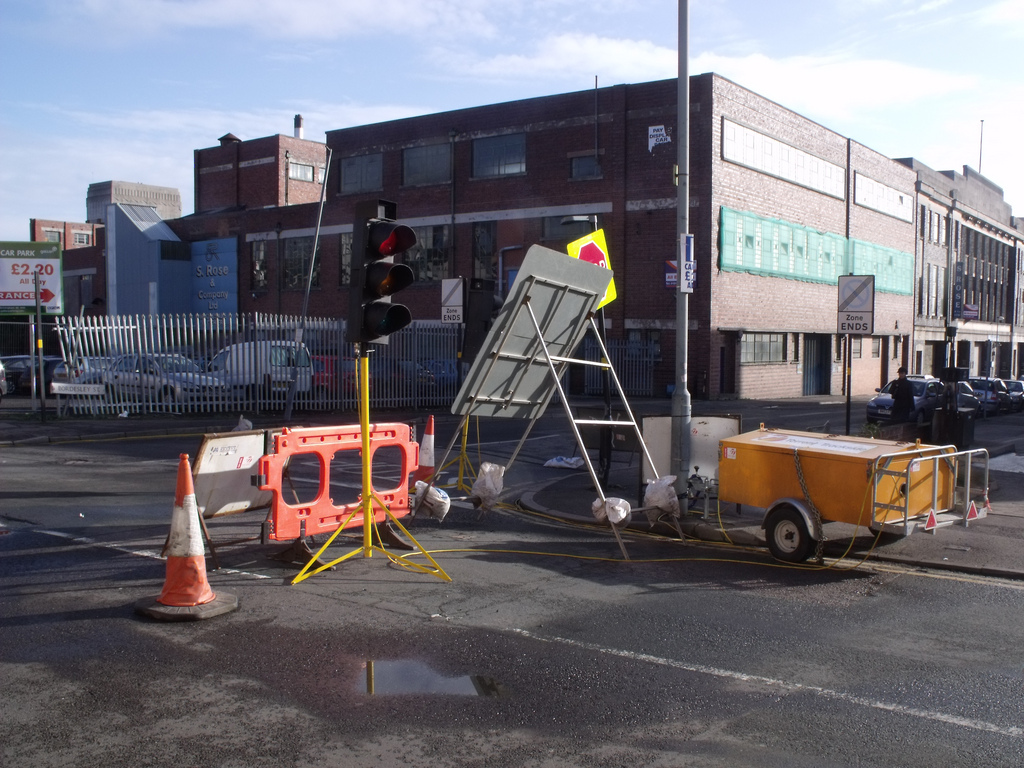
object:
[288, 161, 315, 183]
window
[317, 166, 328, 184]
window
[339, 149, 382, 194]
window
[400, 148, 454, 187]
window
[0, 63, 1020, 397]
building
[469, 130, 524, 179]
window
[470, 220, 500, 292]
window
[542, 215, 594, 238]
window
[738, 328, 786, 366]
window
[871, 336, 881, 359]
window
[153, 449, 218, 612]
traffic cone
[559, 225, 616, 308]
sign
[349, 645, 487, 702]
puddle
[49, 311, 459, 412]
fence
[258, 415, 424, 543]
barrier section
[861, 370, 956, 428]
car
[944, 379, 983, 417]
car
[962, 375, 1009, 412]
car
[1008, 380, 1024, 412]
car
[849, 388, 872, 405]
curb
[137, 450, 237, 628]
cone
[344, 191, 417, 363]
traffic signal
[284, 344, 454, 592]
yellow pole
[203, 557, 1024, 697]
ground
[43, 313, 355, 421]
fence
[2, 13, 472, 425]
background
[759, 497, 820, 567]
wheel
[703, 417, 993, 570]
cart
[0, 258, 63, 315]
sign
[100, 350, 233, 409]
car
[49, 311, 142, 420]
fence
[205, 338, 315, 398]
white van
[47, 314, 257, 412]
fence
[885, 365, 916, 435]
person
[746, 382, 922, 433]
street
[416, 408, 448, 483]
cone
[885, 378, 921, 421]
dress